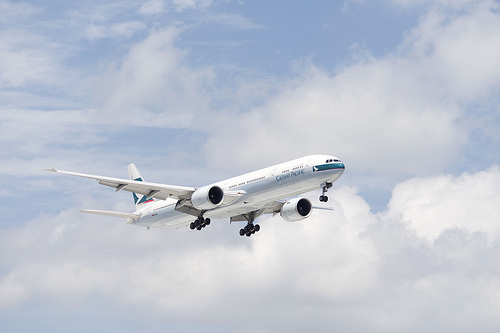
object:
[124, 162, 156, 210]
blue/plane tail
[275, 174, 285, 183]
graphic part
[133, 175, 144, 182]
blue design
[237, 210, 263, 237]
plane/landing gear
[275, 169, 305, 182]
writing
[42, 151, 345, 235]
plane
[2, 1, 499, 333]
sky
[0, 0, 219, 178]
clouds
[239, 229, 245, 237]
tires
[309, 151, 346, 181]
front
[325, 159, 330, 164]
windows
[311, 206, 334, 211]
wing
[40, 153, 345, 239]
airplane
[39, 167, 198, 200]
wing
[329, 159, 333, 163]
windows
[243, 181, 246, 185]
windows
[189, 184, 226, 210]
engine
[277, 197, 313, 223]
engine